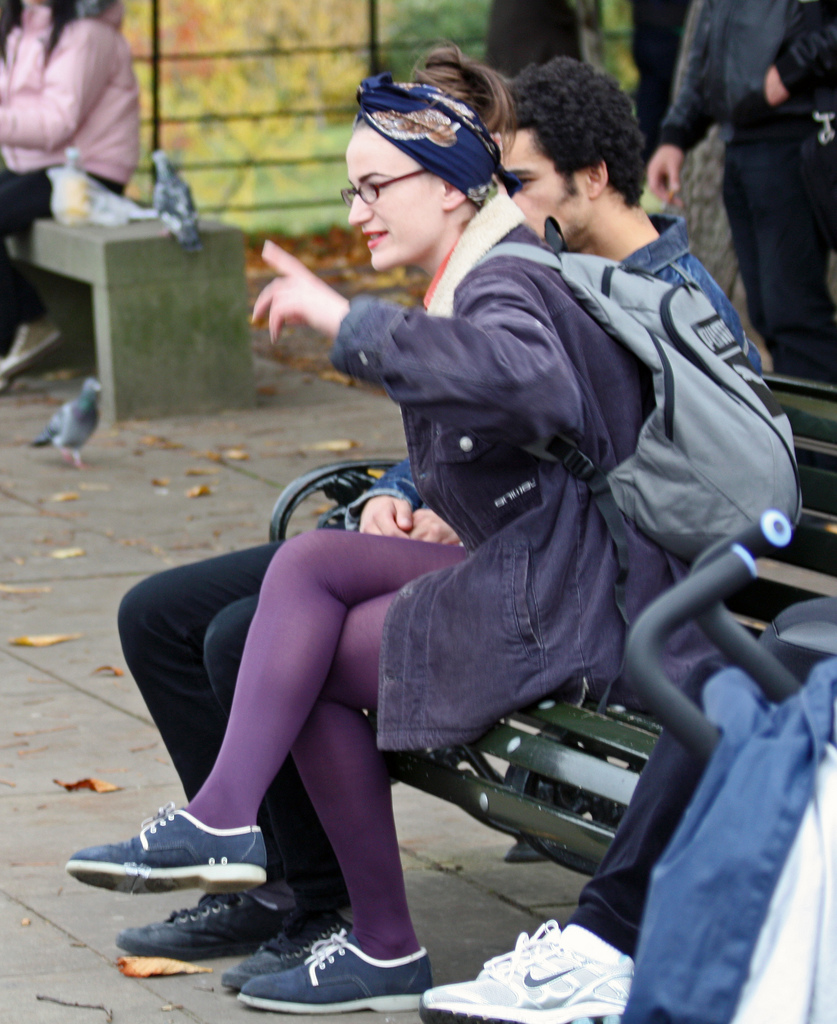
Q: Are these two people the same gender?
A: Yes, all the people are female.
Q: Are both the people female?
A: Yes, all the people are female.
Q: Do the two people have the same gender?
A: Yes, all the people are female.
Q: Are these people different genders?
A: No, all the people are female.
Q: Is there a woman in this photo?
A: Yes, there is a woman.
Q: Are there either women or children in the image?
A: Yes, there is a woman.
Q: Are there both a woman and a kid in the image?
A: No, there is a woman but no children.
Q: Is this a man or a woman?
A: This is a woman.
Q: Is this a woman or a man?
A: This is a woman.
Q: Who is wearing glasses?
A: The woman is wearing glasses.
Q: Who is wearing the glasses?
A: The woman is wearing glasses.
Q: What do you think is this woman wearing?
A: The woman is wearing glasses.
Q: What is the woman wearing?
A: The woman is wearing glasses.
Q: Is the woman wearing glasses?
A: Yes, the woman is wearing glasses.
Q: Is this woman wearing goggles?
A: No, the woman is wearing glasses.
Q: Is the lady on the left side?
A: Yes, the lady is on the left of the image.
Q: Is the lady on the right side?
A: No, the lady is on the left of the image.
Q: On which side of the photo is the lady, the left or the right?
A: The lady is on the left of the image.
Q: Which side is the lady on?
A: The lady is on the left of the image.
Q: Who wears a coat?
A: The lady wears a coat.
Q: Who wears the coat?
A: The lady wears a coat.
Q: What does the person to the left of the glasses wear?
A: The lady wears a coat.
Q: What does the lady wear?
A: The lady wears a coat.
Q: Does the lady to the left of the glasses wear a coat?
A: Yes, the lady wears a coat.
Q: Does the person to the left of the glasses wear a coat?
A: Yes, the lady wears a coat.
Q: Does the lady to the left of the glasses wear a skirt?
A: No, the lady wears a coat.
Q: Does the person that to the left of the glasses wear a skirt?
A: No, the lady wears a coat.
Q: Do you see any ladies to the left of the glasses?
A: Yes, there is a lady to the left of the glasses.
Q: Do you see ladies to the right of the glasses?
A: No, the lady is to the left of the glasses.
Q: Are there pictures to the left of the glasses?
A: No, there is a lady to the left of the glasses.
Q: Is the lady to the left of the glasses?
A: Yes, the lady is to the left of the glasses.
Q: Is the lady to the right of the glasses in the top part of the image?
A: No, the lady is to the left of the glasses.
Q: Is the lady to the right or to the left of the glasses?
A: The lady is to the left of the glasses.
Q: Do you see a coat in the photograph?
A: Yes, there is a coat.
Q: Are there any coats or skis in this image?
A: Yes, there is a coat.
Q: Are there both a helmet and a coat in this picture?
A: No, there is a coat but no helmets.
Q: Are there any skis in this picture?
A: No, there are no skis.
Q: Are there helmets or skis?
A: No, there are no skis or helmets.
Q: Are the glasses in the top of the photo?
A: Yes, the glasses are in the top of the image.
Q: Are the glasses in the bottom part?
A: No, the glasses are in the top of the image.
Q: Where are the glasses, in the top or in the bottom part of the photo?
A: The glasses are in the top of the image.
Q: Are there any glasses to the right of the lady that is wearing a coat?
A: Yes, there are glasses to the right of the lady.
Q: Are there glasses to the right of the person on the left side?
A: Yes, there are glasses to the right of the lady.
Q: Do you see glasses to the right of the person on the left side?
A: Yes, there are glasses to the right of the lady.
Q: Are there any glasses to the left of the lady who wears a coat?
A: No, the glasses are to the right of the lady.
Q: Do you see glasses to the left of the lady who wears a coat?
A: No, the glasses are to the right of the lady.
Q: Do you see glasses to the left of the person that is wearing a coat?
A: No, the glasses are to the right of the lady.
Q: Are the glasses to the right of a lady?
A: Yes, the glasses are to the right of a lady.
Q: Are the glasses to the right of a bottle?
A: No, the glasses are to the right of a lady.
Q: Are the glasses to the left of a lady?
A: No, the glasses are to the right of a lady.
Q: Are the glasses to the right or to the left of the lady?
A: The glasses are to the right of the lady.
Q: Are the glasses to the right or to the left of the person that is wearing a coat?
A: The glasses are to the right of the lady.